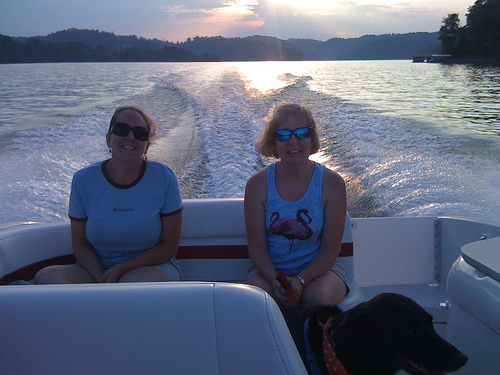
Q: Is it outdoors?
A: Yes, it is outdoors.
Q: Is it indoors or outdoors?
A: It is outdoors.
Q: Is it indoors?
A: No, it is outdoors.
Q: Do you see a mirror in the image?
A: No, there are no mirrors.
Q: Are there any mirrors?
A: No, there are no mirrors.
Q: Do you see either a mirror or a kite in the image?
A: No, there are no mirrors or kites.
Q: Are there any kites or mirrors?
A: No, there are no mirrors or kites.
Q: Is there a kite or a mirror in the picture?
A: No, there are no mirrors or kites.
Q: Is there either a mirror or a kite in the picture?
A: No, there are no mirrors or kites.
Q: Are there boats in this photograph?
A: Yes, there is a boat.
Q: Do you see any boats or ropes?
A: Yes, there is a boat.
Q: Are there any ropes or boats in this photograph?
A: Yes, there is a boat.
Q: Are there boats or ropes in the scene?
A: Yes, there is a boat.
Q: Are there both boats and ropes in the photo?
A: No, there is a boat but no ropes.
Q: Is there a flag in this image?
A: No, there are no flags.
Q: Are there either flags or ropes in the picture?
A: No, there are no flags or ropes.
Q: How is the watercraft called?
A: The watercraft is a boat.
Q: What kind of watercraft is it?
A: The watercraft is a boat.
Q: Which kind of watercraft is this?
A: This is a boat.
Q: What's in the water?
A: The boat is in the water.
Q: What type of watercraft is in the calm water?
A: The watercraft is a boat.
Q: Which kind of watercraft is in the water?
A: The watercraft is a boat.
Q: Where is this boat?
A: The boat is in the water.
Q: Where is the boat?
A: The boat is in the water.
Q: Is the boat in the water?
A: Yes, the boat is in the water.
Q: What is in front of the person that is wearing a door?
A: The boat is in front of the woman.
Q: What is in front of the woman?
A: The boat is in front of the woman.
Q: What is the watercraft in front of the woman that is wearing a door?
A: The watercraft is a boat.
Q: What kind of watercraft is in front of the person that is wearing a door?
A: The watercraft is a boat.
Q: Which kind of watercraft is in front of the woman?
A: The watercraft is a boat.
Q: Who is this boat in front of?
A: The boat is in front of the woman.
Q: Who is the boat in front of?
A: The boat is in front of the woman.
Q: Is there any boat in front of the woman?
A: Yes, there is a boat in front of the woman.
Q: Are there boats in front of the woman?
A: Yes, there is a boat in front of the woman.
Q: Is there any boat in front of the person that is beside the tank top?
A: Yes, there is a boat in front of the woman.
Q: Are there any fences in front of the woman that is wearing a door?
A: No, there is a boat in front of the woman.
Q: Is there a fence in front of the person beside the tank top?
A: No, there is a boat in front of the woman.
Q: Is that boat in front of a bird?
A: No, the boat is in front of a woman.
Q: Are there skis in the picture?
A: No, there are no skis.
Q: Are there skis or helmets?
A: No, there are no skis or helmets.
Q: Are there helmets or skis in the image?
A: No, there are no skis or helmets.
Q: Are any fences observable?
A: No, there are no fences.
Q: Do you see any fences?
A: No, there are no fences.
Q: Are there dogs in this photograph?
A: Yes, there is a dog.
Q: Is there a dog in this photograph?
A: Yes, there is a dog.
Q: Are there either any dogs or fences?
A: Yes, there is a dog.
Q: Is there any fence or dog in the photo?
A: Yes, there is a dog.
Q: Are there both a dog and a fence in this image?
A: No, there is a dog but no fences.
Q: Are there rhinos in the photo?
A: No, there are no rhinos.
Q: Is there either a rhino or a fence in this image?
A: No, there are no rhinos or fences.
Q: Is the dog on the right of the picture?
A: Yes, the dog is on the right of the image.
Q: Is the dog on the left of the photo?
A: No, the dog is on the right of the image.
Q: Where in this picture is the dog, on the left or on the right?
A: The dog is on the right of the image.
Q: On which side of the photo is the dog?
A: The dog is on the right of the image.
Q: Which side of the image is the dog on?
A: The dog is on the right of the image.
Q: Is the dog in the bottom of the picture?
A: Yes, the dog is in the bottom of the image.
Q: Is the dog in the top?
A: No, the dog is in the bottom of the image.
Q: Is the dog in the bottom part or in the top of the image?
A: The dog is in the bottom of the image.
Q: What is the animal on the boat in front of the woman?
A: The animal is a dog.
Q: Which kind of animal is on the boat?
A: The animal is a dog.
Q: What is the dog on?
A: The dog is on the boat.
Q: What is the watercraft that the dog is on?
A: The watercraft is a boat.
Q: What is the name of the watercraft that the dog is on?
A: The watercraft is a boat.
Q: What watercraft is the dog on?
A: The dog is on the boat.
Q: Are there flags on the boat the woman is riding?
A: No, there is a dog on the boat.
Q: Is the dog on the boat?
A: Yes, the dog is on the boat.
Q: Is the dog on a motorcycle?
A: No, the dog is on the boat.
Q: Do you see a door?
A: Yes, there is a door.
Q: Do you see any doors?
A: Yes, there is a door.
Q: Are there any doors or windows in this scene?
A: Yes, there is a door.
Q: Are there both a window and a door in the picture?
A: No, there is a door but no windows.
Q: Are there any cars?
A: No, there are no cars.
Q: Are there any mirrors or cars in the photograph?
A: No, there are no cars or mirrors.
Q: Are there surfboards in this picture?
A: No, there are no surfboards.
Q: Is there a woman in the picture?
A: Yes, there is a woman.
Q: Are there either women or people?
A: Yes, there is a woman.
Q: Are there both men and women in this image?
A: No, there is a woman but no men.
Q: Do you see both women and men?
A: No, there is a woman but no men.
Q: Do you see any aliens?
A: No, there are no aliens.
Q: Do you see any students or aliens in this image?
A: No, there are no aliens or students.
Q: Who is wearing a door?
A: The woman is wearing a door.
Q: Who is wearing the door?
A: The woman is wearing a door.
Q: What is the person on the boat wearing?
A: The woman is wearing a door.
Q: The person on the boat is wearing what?
A: The woman is wearing a door.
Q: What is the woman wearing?
A: The woman is wearing a door.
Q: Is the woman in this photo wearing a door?
A: Yes, the woman is wearing a door.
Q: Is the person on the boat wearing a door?
A: Yes, the woman is wearing a door.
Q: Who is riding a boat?
A: The woman is riding a boat.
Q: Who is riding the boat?
A: The woman is riding a boat.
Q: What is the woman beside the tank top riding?
A: The woman is riding a boat.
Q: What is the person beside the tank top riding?
A: The woman is riding a boat.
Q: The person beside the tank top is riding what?
A: The woman is riding a boat.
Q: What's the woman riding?
A: The woman is riding a boat.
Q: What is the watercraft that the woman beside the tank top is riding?
A: The watercraft is a boat.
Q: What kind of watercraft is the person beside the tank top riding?
A: The woman is riding a boat.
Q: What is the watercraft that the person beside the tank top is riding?
A: The watercraft is a boat.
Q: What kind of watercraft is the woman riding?
A: The woman is riding a boat.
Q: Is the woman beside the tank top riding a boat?
A: Yes, the woman is riding a boat.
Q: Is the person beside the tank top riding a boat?
A: Yes, the woman is riding a boat.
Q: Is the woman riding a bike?
A: No, the woman is riding a boat.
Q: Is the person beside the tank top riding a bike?
A: No, the woman is riding a boat.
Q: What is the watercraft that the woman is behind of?
A: The watercraft is a boat.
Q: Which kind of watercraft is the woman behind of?
A: The woman is behind the boat.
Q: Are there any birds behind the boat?
A: No, there is a woman behind the boat.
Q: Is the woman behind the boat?
A: Yes, the woman is behind the boat.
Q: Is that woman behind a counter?
A: No, the woman is behind the boat.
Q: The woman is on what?
A: The woman is on the boat.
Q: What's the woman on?
A: The woman is on the boat.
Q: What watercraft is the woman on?
A: The woman is on the boat.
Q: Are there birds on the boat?
A: No, there is a woman on the boat.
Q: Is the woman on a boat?
A: Yes, the woman is on a boat.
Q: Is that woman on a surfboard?
A: No, the woman is on a boat.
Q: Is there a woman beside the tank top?
A: Yes, there is a woman beside the tank top.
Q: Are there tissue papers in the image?
A: No, there are no tissue papers.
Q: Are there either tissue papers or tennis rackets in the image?
A: No, there are no tissue papers or tennis rackets.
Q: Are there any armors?
A: No, there are no armors.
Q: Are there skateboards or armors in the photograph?
A: No, there are no armors or skateboards.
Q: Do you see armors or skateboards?
A: No, there are no armors or skateboards.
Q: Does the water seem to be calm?
A: Yes, the water is calm.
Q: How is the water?
A: The water is calm.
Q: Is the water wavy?
A: No, the water is calm.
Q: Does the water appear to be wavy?
A: No, the water is calm.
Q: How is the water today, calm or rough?
A: The water is calm.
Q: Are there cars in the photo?
A: No, there are no cars.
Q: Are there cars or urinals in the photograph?
A: No, there are no cars or urinals.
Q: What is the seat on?
A: The seat is on the boat.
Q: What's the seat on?
A: The seat is on the boat.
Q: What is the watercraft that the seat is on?
A: The watercraft is a boat.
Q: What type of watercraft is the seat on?
A: The seat is on the boat.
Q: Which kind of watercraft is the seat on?
A: The seat is on the boat.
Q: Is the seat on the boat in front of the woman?
A: Yes, the seat is on the boat.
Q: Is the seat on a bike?
A: No, the seat is on the boat.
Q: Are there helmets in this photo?
A: No, there are no helmets.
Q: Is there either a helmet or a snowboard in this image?
A: No, there are no helmets or snowboards.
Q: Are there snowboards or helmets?
A: No, there are no helmets or snowboards.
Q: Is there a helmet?
A: No, there are no helmets.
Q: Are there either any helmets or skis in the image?
A: No, there are no helmets or skis.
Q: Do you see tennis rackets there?
A: No, there are no tennis rackets.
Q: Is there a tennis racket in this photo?
A: No, there are no rackets.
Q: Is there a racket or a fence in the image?
A: No, there are no rackets or fences.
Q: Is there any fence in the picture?
A: No, there are no fences.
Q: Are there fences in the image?
A: No, there are no fences.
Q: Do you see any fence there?
A: No, there are no fences.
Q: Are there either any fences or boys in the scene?
A: No, there are no fences or boys.